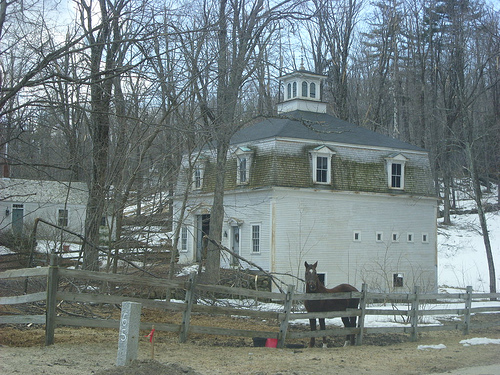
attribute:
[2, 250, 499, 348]
wood fence — wooden 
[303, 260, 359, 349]
horse — brown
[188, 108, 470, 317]
house — white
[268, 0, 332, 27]
branch —  tree's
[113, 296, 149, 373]
marker — painted 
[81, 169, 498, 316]
snow — White 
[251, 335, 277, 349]
buckets — black and red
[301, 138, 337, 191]
window — side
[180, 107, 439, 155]
roof — grey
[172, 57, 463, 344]
barn — old 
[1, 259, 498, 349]
fence — Gray , Wooden 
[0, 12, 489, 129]
sky — White 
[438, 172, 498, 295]
snow — white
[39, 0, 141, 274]
tree — Bare 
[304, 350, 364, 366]
grass — Green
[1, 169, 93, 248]
building — White 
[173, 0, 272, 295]
tree — deciduous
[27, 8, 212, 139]
branch —  tree's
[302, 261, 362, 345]
horse — Brown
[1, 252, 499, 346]
fence — wooden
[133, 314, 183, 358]
flag — Red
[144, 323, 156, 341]
marker — red 